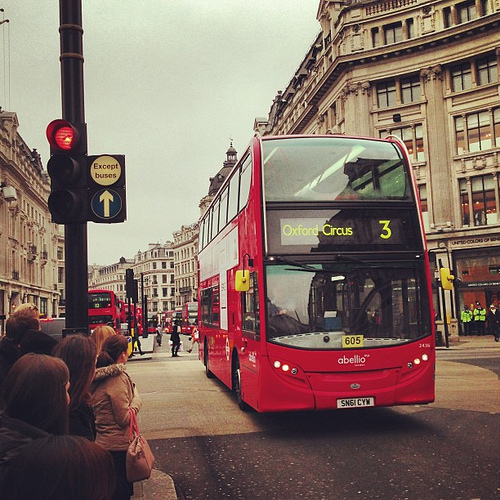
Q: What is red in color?
A: The bus.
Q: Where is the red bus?
A: On the street.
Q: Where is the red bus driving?
A: On the road.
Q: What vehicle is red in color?
A: Bus.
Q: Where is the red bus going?
A: Oxford Circus.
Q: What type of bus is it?
A: Double decker.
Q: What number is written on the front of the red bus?
A: 605.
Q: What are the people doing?
A: Waiting for the red bus.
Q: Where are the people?
A: On the sidewalk.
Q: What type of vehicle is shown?
A: A bus.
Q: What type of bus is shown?
A: A double decker.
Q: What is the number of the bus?
A: 3.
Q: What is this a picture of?
A: A bus.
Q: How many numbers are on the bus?
A: One.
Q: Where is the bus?
A: On the street.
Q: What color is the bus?
A: Red.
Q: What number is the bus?
A: Three.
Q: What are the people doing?
A: Waiting for the bus.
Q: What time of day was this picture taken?
A: Daytime.